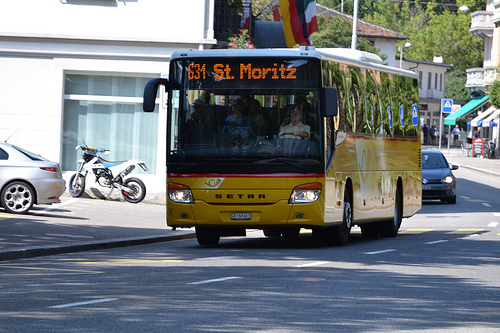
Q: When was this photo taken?
A: Daytime.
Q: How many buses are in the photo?
A: One.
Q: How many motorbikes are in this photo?
A: One.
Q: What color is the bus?
A: Yellow.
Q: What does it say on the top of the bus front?
A: 631 St. Moritz.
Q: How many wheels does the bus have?
A: Four.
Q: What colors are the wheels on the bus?
A: Black.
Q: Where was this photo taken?
A: On the street.